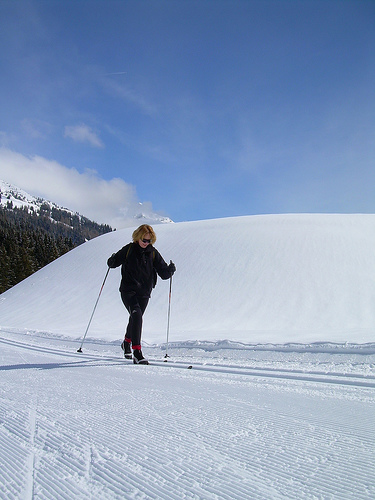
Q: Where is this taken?
A: In a ski area.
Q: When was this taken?
A: Day time.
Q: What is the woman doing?
A: Skiing.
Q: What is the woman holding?
A: Ski poles.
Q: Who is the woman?
A: A skier.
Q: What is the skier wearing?
A: Black clothes.